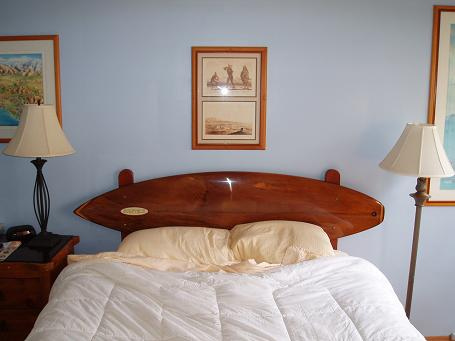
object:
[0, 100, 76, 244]
lamp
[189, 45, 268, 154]
picture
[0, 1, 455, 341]
wall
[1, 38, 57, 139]
picture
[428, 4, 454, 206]
picture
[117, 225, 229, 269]
pillow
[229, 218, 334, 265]
pillow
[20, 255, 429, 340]
comforter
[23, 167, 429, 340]
bed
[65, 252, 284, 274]
sheet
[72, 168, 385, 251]
headboard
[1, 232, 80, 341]
nightstand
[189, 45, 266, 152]
frame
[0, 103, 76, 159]
lamp shade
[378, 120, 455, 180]
lamp shade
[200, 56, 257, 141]
artwork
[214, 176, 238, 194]
light reflection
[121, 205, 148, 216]
sticker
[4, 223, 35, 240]
alarm clock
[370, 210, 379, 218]
circle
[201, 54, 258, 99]
picture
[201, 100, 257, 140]
picture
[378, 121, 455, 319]
floor lamp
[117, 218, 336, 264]
pillows